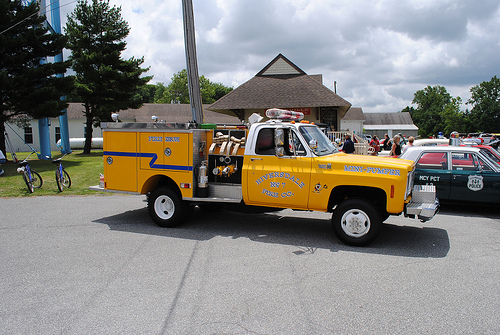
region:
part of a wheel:
[336, 200, 385, 259]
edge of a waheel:
[370, 220, 385, 245]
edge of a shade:
[167, 227, 203, 260]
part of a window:
[305, 132, 325, 145]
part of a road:
[244, 242, 287, 274]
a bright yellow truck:
[93, 109, 430, 247]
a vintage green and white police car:
[394, 132, 498, 206]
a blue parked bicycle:
[49, 155, 72, 192]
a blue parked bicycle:
[9, 152, 46, 189]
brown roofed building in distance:
[120, 52, 362, 133]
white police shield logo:
[464, 170, 484, 192]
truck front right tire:
[329, 197, 379, 245]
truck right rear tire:
[142, 182, 183, 228]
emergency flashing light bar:
[264, 107, 306, 120]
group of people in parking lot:
[366, 131, 415, 158]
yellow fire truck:
[91, 98, 437, 246]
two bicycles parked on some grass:
[15, 150, 75, 195]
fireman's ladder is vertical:
[175, 0, 205, 130]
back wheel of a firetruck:
[142, 184, 192, 228]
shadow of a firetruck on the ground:
[91, 196, 458, 266]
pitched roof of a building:
[200, 51, 353, 113]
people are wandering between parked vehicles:
[334, 127, 418, 157]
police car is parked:
[378, 142, 498, 215]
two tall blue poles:
[32, 2, 76, 162]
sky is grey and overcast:
[51, 1, 496, 114]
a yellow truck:
[82, 104, 439, 256]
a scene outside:
[1, 1, 498, 318]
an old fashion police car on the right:
[366, 127, 497, 254]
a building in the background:
[204, 33, 372, 188]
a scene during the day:
[21, 10, 493, 302]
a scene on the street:
[16, 11, 481, 333]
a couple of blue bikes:
[3, 122, 99, 203]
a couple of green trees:
[2, 2, 190, 174]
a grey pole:
[140, 0, 216, 163]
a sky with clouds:
[49, 5, 498, 140]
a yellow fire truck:
[113, 122, 459, 280]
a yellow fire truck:
[138, 139, 314, 280]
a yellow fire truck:
[209, 140, 274, 230]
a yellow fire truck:
[173, 62, 349, 279]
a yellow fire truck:
[176, 103, 255, 185]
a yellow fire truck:
[216, 150, 321, 292]